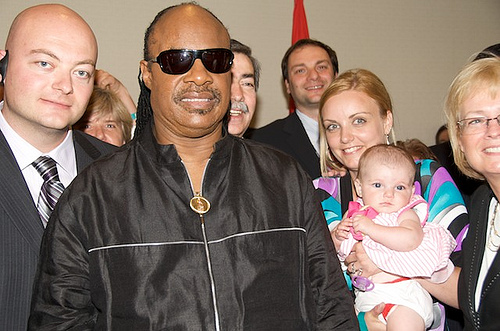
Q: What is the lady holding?
A: Baby.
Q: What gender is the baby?
A: Gird.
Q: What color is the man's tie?
A: Striped black and white.